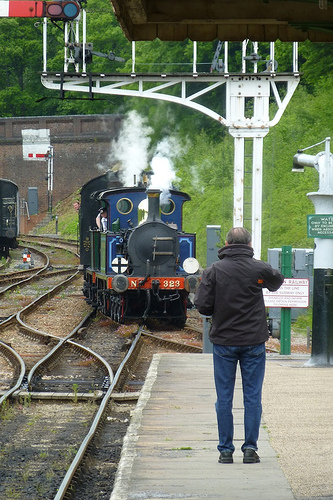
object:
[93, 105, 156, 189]
steam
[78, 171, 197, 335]
train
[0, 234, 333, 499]
ground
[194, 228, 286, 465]
man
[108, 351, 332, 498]
platform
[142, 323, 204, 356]
tracks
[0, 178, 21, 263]
train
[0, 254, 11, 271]
tracks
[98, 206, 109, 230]
conductor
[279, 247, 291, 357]
pole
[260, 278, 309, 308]
sign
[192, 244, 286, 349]
jacket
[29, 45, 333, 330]
hill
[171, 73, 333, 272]
grass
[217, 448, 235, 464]
shoes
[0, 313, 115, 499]
tracks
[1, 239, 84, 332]
tracks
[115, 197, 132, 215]
window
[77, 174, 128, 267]
caboose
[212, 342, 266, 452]
blue jeans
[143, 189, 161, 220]
smoke stack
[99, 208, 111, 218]
head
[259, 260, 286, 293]
arm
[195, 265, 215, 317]
arm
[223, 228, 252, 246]
head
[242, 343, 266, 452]
leg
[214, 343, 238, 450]
leg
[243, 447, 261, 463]
feet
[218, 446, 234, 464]
feet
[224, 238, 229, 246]
ear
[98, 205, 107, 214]
hat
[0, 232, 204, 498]
several directions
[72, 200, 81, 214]
man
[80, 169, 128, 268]
rear of train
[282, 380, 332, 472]
air